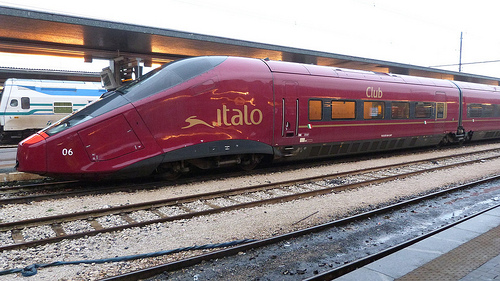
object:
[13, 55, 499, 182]
train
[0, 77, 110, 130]
train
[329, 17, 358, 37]
sky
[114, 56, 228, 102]
window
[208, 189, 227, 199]
tracks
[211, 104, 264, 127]
logo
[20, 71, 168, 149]
nose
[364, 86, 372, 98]
word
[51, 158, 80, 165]
umber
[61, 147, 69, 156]
number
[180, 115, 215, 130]
bunny